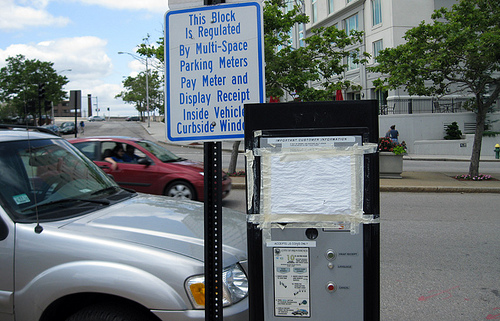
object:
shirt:
[110, 154, 128, 164]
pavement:
[379, 190, 499, 320]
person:
[79, 120, 86, 135]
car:
[67, 136, 233, 203]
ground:
[418, 153, 462, 190]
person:
[102, 144, 126, 171]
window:
[100, 141, 154, 166]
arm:
[105, 156, 118, 170]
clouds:
[0, 0, 70, 30]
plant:
[391, 146, 406, 155]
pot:
[380, 151, 403, 177]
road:
[77, 115, 498, 175]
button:
[325, 281, 336, 293]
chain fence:
[380, 96, 474, 114]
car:
[1, 124, 252, 320]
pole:
[72, 90, 79, 139]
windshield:
[0, 138, 119, 218]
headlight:
[190, 283, 205, 304]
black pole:
[202, 142, 224, 320]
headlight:
[220, 260, 249, 306]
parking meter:
[243, 98, 381, 320]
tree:
[0, 53, 70, 125]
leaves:
[6, 73, 26, 85]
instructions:
[272, 246, 312, 317]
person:
[385, 124, 399, 139]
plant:
[379, 137, 394, 151]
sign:
[163, 1, 265, 145]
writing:
[187, 13, 206, 26]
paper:
[261, 149, 363, 222]